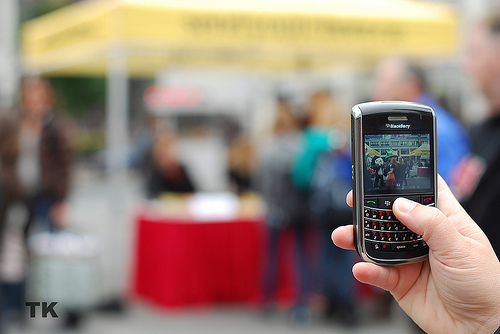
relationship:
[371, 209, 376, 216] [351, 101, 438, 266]
number on phone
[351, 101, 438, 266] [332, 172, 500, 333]
phone held by a man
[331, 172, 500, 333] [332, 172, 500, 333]
hand from a man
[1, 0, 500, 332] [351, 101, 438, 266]
picture being taken by a phone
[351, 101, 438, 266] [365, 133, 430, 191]
phone has a screen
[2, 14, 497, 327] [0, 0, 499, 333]
people in background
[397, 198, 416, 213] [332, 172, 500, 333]
fingernail on man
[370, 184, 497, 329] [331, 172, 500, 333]
wrinkles on hand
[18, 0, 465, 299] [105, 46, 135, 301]
tent has a pole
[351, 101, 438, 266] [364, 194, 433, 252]
phone has buttons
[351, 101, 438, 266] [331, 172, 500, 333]
phone in persons hand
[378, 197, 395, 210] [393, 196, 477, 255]
button getting pressed by a thumb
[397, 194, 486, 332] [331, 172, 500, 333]
palm on hand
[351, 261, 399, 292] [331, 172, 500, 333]
pinky finger on hand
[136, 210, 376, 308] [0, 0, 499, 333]
table in background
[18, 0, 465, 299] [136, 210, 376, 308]
tent above table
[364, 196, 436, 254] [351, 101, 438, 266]
keyboard on phone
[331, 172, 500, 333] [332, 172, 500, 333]
hand on man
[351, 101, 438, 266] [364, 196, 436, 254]
phone has a keyboard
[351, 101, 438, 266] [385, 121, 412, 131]
phone has a logo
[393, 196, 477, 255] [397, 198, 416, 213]
thumb has a fingernail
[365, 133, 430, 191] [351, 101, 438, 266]
screen on phone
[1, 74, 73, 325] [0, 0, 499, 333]
bystander in background